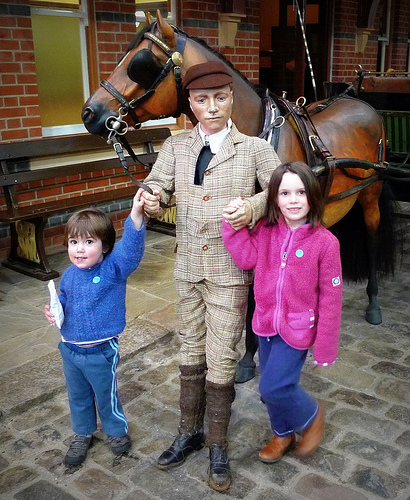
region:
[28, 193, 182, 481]
a small boy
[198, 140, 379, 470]
a small girl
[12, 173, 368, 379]
two small children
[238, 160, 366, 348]
a small girl wearing a pink jacket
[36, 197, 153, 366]
a small boy wearing a blue sweater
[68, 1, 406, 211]
a brown horse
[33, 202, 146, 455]
a small boy wearing blue pants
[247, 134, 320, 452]
a small girl wearing blue pants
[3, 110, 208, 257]
a wooden bench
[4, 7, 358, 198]
a brick building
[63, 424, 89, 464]
the shoe of a little boy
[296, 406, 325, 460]
a girl's brown shoe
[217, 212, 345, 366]
a girl's pink and white jacket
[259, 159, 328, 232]
the head of a little girl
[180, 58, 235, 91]
a brown hat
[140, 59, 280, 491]
a statue of a man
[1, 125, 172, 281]
part of a wooden bench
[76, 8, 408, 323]
a brown and black horse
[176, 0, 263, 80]
part of a red brick building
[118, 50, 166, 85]
a black eye patch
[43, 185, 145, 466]
young boy wearing all blue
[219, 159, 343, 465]
young girl wearing a pink jacket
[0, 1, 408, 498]
two young children posing with a fake man and horse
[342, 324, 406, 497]
brick paved street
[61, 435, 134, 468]
child's tennis shoes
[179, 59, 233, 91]
brown hat with a bill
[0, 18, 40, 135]
side of a brick building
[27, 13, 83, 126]
frosted window glass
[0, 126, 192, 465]
boy in front of a bench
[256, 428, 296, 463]
girl's right boot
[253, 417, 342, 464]
girls' brown leather boots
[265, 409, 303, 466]
girls' brown leather boots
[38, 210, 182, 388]
boy wearing blue sweater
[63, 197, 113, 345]
boy wearing blue sweater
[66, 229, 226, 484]
boy wearing blue sweater